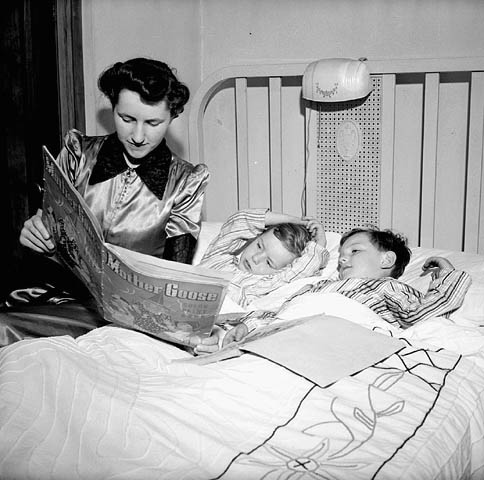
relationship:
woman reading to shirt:
[18, 57, 211, 306] [211, 211, 321, 316]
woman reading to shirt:
[18, 57, 211, 306] [290, 276, 468, 319]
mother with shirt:
[18, 57, 211, 306] [211, 211, 321, 316]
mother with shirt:
[18, 57, 211, 306] [290, 276, 468, 319]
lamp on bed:
[299, 59, 377, 109] [188, 72, 483, 263]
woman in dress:
[18, 57, 211, 306] [53, 132, 206, 265]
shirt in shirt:
[211, 211, 321, 316] [211, 211, 321, 316]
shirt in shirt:
[290, 276, 468, 319] [290, 276, 468, 319]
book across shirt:
[186, 316, 406, 387] [290, 276, 468, 319]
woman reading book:
[18, 57, 211, 306] [38, 146, 228, 344]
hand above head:
[306, 220, 324, 243] [238, 224, 312, 266]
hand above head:
[292, 215, 313, 226] [238, 224, 312, 266]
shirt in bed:
[211, 211, 321, 316] [188, 72, 483, 263]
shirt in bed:
[290, 276, 468, 319] [188, 72, 483, 263]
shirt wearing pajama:
[290, 276, 468, 319] [290, 276, 468, 319]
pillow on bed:
[347, 232, 483, 327] [188, 72, 483, 263]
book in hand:
[38, 146, 228, 344] [19, 209, 58, 259]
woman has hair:
[18, 57, 211, 306] [96, 63, 193, 110]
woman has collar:
[18, 57, 211, 306] [92, 132, 173, 196]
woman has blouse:
[18, 57, 211, 306] [53, 132, 206, 265]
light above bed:
[299, 59, 377, 109] [188, 72, 483, 263]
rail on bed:
[231, 80, 255, 212] [188, 72, 483, 263]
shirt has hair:
[211, 211, 321, 316] [341, 230, 411, 279]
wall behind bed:
[80, 3, 478, 247] [188, 72, 483, 263]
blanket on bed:
[5, 303, 477, 479] [188, 72, 483, 263]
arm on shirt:
[386, 258, 471, 321] [290, 276, 468, 319]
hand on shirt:
[426, 251, 454, 277] [290, 276, 468, 319]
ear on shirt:
[382, 250, 398, 273] [290, 276, 468, 319]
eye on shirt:
[352, 246, 363, 257] [290, 276, 468, 319]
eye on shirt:
[251, 241, 263, 253] [211, 211, 321, 316]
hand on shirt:
[292, 215, 313, 226] [211, 211, 321, 316]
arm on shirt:
[212, 208, 309, 236] [211, 211, 321, 316]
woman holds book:
[18, 57, 211, 306] [38, 146, 228, 344]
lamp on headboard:
[299, 59, 377, 109] [188, 72, 483, 263]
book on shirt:
[186, 316, 406, 387] [290, 276, 468, 319]